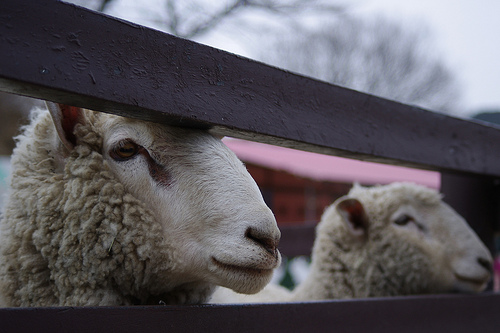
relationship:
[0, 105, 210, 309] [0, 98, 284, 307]
wool of sheep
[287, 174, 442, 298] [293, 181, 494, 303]
wool of sheep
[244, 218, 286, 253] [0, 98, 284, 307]
nose of sheep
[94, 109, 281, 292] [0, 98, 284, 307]
face of sheep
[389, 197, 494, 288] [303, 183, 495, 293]
face of sheep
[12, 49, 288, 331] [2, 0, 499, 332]
sheep looking through fence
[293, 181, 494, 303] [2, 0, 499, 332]
sheep looking through fence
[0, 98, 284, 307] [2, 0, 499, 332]
sheep looking through fence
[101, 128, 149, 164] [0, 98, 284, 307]
eye of sheep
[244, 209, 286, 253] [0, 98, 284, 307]
nose on sheep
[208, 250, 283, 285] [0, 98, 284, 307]
mouth on sheep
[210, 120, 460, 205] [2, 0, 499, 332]
roof behind fence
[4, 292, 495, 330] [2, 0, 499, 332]
board on fence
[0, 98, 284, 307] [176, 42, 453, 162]
sheep looking through fence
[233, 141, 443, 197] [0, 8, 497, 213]
building in background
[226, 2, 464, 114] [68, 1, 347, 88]
tree looking tree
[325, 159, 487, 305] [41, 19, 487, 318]
sheep looking fence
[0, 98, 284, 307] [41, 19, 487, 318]
sheep looking fence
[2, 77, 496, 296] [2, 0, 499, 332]
two sheep by fence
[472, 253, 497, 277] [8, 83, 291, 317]
sheep's nose by sheep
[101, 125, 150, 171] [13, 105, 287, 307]
eye on sheep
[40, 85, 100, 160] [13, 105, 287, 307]
ear on sheep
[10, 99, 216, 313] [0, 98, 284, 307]
fur on sheep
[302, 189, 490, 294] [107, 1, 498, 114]
sheep background in background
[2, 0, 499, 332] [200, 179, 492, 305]
fence in front of sheep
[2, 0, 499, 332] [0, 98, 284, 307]
fence in front of sheep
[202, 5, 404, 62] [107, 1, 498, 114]
trees in background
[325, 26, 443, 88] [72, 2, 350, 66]
leaves on trees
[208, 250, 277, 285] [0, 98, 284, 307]
mouth of sheep